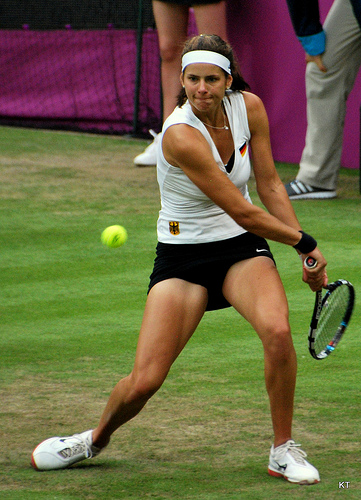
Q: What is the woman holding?
A: A racket.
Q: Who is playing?
A: A woman.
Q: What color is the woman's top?
A: White.